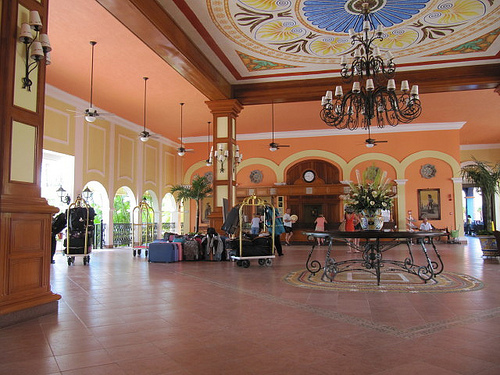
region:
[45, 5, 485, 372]
this is a lobby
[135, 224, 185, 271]
this is a suitcase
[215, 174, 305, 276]
suitcases on a cart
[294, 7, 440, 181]
this is a chandelier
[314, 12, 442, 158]
the chandelier is black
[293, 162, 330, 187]
this is a clock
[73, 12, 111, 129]
this is a pendant light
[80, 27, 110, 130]
pendant light is black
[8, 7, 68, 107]
sconce on the wall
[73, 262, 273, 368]
tile on the floor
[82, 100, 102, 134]
pendant light hanging from ceiling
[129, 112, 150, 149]
pendant light hanging from ceiling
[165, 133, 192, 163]
pendant light hanging from ceiling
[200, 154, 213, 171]
pendant light hanging from ceiling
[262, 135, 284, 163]
pendant light hanging from ceiling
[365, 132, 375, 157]
pendant light hanging from ceiling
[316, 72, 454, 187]
chandelier hanging from ceiling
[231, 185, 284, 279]
luggage on the cart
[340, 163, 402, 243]
flowers in a pot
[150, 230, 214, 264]
suitcases on the floor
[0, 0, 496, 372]
fancy hotel lobby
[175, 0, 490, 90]
intricate design on the cieling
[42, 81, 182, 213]
yellow walls with white moulding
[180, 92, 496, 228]
peach walls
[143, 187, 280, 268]
a pile of luggage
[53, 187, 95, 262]
luggage on a trolley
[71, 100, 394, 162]
fans hanging from the ceiling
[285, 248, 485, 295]
intricate design underneath the circular table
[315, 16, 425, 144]
large chandelier over table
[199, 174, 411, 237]
check-in counter at back of hotel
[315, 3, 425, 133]
Chandelier hanging from ceiling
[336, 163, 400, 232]
Large plant in vase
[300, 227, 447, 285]
Table in middle of hotel lobby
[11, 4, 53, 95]
Lighting fixture on wall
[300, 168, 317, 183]
Black rimmed wall clock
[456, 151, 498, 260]
Large floor plant on tiled floor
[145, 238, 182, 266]
Blue suitcase sitting on floor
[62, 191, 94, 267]
Wheeled cart holding suitcases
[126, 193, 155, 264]
Empty wheeled cart in hotel lobby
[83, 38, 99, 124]
Light fixture hanging from ceiling